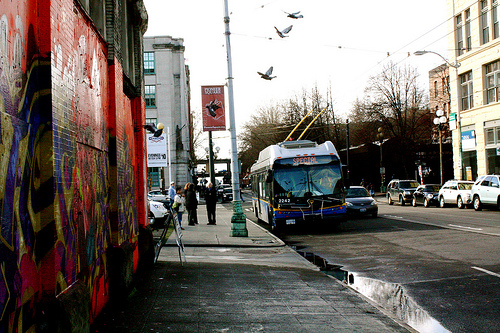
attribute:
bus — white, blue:
[250, 142, 350, 232]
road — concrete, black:
[226, 190, 498, 332]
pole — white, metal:
[223, 1, 246, 234]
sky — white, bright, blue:
[142, 3, 443, 111]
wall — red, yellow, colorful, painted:
[1, 2, 147, 332]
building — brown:
[425, 66, 456, 116]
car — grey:
[342, 186, 377, 212]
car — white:
[437, 182, 472, 204]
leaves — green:
[254, 120, 337, 140]